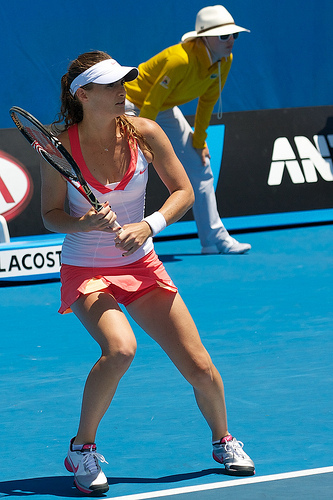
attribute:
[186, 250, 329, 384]
tennis court — blue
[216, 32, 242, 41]
sunglasses — white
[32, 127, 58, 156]
w — red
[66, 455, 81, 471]
sign — pink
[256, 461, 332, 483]
line — white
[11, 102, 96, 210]
racket — black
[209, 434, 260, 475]
shoe — white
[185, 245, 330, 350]
tennis court — blue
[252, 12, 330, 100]
barricade — blue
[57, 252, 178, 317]
skirt — pink